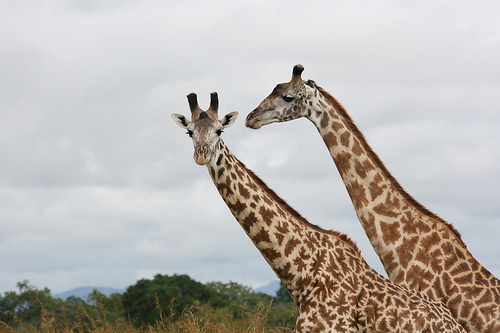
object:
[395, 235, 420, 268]
brown spot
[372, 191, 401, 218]
brown spot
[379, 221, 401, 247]
brown spot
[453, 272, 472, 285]
brown spot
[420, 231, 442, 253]
brown spot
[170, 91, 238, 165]
head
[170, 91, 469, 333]
giraffe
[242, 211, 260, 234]
brown spot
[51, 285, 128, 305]
mountain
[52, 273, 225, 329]
trees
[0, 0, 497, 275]
sky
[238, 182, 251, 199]
spot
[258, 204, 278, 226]
spot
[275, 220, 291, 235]
spot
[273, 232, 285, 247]
spot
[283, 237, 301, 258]
spot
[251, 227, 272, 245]
spot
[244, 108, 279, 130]
mouth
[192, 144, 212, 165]
mouth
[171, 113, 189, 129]
ear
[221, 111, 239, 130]
ear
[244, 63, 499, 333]
giraffe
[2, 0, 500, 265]
clouds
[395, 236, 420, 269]
spot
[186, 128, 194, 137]
eyes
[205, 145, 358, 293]
neck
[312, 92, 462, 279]
neck